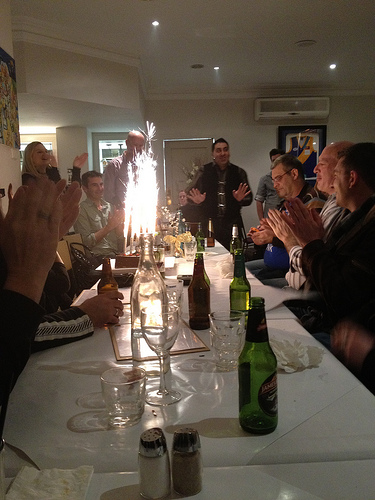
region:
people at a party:
[1, 101, 373, 448]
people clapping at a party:
[241, 143, 373, 328]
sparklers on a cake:
[117, 116, 169, 269]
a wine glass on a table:
[138, 307, 190, 412]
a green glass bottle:
[234, 295, 284, 433]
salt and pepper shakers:
[136, 419, 208, 498]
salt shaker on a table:
[133, 419, 169, 499]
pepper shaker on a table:
[170, 423, 206, 498]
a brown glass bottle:
[187, 258, 210, 327]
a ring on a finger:
[34, 204, 54, 226]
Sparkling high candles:
[128, 149, 158, 249]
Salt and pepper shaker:
[132, 426, 212, 498]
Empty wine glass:
[141, 305, 189, 406]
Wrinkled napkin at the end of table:
[274, 338, 325, 373]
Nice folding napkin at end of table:
[5, 466, 85, 498]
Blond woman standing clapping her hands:
[20, 138, 81, 181]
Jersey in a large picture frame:
[275, 125, 321, 170]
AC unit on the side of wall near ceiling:
[258, 97, 329, 116]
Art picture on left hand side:
[0, 48, 20, 146]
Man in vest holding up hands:
[187, 137, 252, 232]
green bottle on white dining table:
[232, 290, 293, 441]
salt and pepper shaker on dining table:
[121, 423, 216, 499]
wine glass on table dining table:
[134, 300, 189, 408]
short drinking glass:
[83, 362, 152, 427]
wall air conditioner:
[248, 91, 343, 121]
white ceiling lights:
[207, 59, 343, 79]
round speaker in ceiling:
[289, 31, 317, 56]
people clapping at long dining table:
[4, 137, 128, 405]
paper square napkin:
[2, 457, 103, 497]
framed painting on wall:
[160, 132, 224, 218]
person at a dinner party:
[180, 130, 260, 247]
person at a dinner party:
[251, 146, 285, 225]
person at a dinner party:
[266, 148, 321, 218]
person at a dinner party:
[98, 128, 151, 253]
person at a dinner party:
[74, 162, 127, 263]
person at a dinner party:
[22, 138, 91, 191]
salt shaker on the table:
[129, 424, 171, 498]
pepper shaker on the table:
[171, 419, 205, 498]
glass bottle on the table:
[233, 288, 279, 442]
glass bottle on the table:
[225, 241, 255, 316]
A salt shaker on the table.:
[136, 427, 170, 499]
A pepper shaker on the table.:
[169, 422, 206, 496]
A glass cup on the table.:
[98, 360, 146, 423]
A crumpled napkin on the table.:
[271, 335, 327, 373]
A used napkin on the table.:
[5, 464, 92, 498]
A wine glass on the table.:
[136, 299, 186, 407]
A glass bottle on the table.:
[234, 295, 282, 436]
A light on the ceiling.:
[326, 60, 339, 71]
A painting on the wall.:
[0, 47, 21, 150]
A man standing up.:
[180, 136, 252, 250]